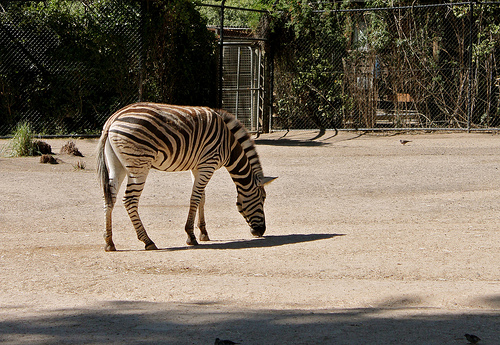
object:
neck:
[225, 145, 265, 183]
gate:
[222, 42, 262, 133]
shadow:
[155, 233, 347, 252]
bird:
[399, 139, 413, 146]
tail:
[93, 129, 114, 208]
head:
[235, 176, 279, 236]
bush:
[0, 0, 116, 15]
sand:
[0, 131, 499, 343]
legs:
[102, 167, 155, 243]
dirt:
[39, 155, 86, 170]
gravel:
[0, 154, 499, 345]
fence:
[0, 0, 499, 139]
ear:
[262, 176, 279, 187]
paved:
[288, 140, 494, 290]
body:
[95, 102, 230, 243]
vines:
[351, 0, 500, 131]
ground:
[0, 124, 499, 344]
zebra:
[92, 101, 280, 251]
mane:
[216, 109, 265, 182]